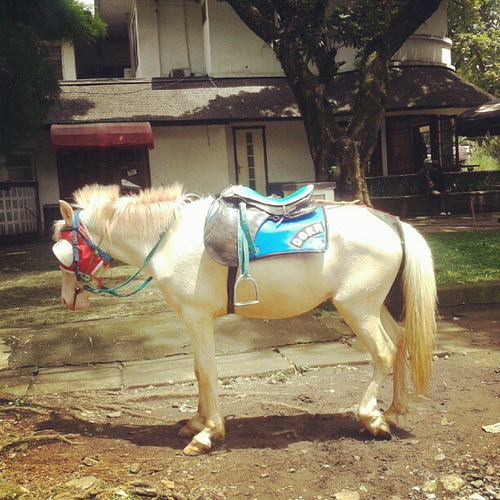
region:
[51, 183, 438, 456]
A pony wearing a saddle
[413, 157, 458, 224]
A man sitting on a bench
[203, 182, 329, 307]
A saddle on a horse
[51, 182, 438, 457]
A bridled horse with a saddle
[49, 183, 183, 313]
A pony with a bridle and blinders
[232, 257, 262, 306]
A stirrup hanging from a saddle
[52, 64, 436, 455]
A horse in front of a building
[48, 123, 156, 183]
An entrance way with an awning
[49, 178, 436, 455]
A racing horse standing on the road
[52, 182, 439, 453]
A mule prepared to ride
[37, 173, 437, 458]
white horse with blue saddle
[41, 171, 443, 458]
white horse with a red blind on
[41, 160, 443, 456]
white horse with blue rein on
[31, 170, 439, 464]
white horse standing on dirt road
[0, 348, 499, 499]
Dirt road horse is standing in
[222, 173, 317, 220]
blue saddle on horse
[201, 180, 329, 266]
blue blanket on horse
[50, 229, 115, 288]
red blind on horse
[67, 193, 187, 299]
blue rein on horse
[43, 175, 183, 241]
Horses white mane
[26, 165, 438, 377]
the horse is white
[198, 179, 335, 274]
the saddle is blue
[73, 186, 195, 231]
horse's mane hair is white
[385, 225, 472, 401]
horse's tail hair is white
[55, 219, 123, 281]
the material is red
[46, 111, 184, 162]
red awning on building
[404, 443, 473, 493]
rocks on the ground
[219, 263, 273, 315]
silver piece on material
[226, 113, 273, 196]
door frame is brown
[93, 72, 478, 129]
the roof is brown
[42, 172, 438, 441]
white horse standing on road way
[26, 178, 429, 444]
white horse with red cover on head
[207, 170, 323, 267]
blue saddle on white horse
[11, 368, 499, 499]
broken roadway horse is standing on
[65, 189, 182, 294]
blue reins of saddle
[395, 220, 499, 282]
patch of grass behind horse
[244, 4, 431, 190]
tree trunk behind horse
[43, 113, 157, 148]
red canopy over door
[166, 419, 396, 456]
hooves of white horse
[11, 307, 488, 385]
sidewalk behind white horse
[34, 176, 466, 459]
a white horse in front a building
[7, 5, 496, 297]
an old building behind a horse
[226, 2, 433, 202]
a tree in front a building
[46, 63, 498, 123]
black roof is decaying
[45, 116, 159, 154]
red awning over a door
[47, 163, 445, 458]
a blue saddle on back a horse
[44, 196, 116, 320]
the face of horse is covered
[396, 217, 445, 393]
a long tail of horse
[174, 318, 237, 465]
front legs of horse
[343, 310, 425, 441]
back legs of horse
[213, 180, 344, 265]
blue saddle on horse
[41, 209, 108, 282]
red blinder on horse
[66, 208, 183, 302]
blue harness on horse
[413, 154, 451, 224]
man sitting on bench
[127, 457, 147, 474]
small rock laying by horse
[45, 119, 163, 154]
red awning over door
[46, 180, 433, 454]
a white horse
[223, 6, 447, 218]
tree in front of house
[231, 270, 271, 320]
white stirrup on saddle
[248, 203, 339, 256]
blue blanket under saddle